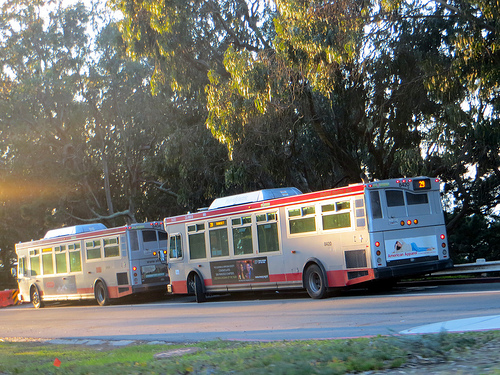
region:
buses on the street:
[2, 205, 402, 310]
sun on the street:
[0, 309, 282, 331]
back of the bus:
[362, 161, 453, 268]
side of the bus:
[9, 240, 141, 304]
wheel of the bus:
[310, 253, 325, 305]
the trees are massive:
[132, 5, 449, 155]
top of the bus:
[28, 213, 105, 239]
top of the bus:
[207, 176, 294, 208]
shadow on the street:
[134, 308, 211, 336]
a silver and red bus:
[161, 173, 449, 303]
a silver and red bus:
[13, 220, 165, 310]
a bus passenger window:
[188, 232, 206, 259]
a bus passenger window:
[208, 230, 229, 258]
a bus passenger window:
[231, 225, 253, 255]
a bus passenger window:
[254, 221, 279, 254]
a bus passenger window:
[288, 218, 315, 234]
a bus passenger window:
[320, 212, 350, 232]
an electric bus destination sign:
[206, 220, 226, 228]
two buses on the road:
[7, 159, 464, 321]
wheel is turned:
[185, 274, 208, 302]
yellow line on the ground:
[332, 290, 499, 300]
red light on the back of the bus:
[368, 236, 386, 246]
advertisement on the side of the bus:
[206, 252, 279, 292]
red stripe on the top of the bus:
[161, 177, 366, 225]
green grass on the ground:
[0, 331, 442, 373]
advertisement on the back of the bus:
[375, 234, 445, 262]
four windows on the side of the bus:
[183, 208, 290, 263]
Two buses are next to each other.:
[6, 167, 462, 321]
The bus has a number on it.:
[399, 170, 442, 196]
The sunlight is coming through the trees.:
[2, 121, 112, 218]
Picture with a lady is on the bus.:
[380, 230, 443, 262]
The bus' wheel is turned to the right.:
[174, 264, 219, 311]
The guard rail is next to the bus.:
[363, 237, 497, 312]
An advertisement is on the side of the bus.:
[205, 251, 275, 289]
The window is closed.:
[276, 202, 323, 237]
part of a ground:
[231, 338, 256, 360]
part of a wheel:
[304, 278, 321, 308]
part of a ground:
[253, 333, 305, 372]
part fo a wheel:
[308, 282, 323, 297]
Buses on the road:
[18, 175, 465, 320]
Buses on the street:
[21, 194, 435, 316]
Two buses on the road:
[23, 198, 447, 310]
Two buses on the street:
[11, 189, 432, 305]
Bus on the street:
[151, 173, 458, 296]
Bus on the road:
[149, 182, 470, 311]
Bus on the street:
[10, 225, 163, 305]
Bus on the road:
[8, 218, 172, 298]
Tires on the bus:
[28, 278, 117, 315]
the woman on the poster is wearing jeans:
[411, 240, 436, 252]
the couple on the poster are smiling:
[238, 261, 254, 279]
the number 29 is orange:
[416, 180, 428, 187]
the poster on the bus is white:
[383, 233, 438, 258]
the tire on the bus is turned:
[192, 273, 203, 306]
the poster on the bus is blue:
[43, 275, 79, 302]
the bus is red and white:
[163, 176, 455, 295]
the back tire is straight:
[303, 265, 323, 301]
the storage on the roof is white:
[207, 185, 300, 202]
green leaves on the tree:
[336, 60, 384, 89]